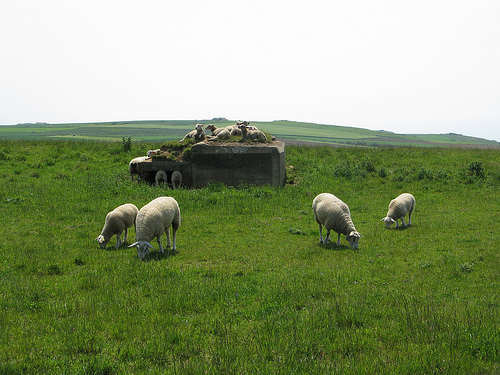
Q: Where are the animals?
A: In a field.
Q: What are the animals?
A: Sheep.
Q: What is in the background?
A: Hills.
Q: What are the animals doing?
A: Grazing.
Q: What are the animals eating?
A: Grass.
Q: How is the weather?
A: Clear.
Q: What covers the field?
A: Grass.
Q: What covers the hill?
A: Grass.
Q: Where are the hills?
A: Behind the sheep.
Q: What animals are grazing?
A: Sheep.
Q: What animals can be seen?
A: Sheep.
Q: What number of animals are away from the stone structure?
A: Four sheep.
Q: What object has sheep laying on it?
A: The concrete wall.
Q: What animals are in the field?
A: Sheep.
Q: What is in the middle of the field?
A: A stone structure.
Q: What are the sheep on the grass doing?
A: Grazing.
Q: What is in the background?
A: Green fields of grass.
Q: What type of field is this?
A: A grassy field.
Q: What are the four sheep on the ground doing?
A: Eating grass.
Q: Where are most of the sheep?
A: On the stone structure.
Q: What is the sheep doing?
A: Grazing.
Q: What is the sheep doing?
A: Eating.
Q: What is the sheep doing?
A: Standing.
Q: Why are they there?
A: Eating.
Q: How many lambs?
A: 4.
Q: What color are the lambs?
A: White.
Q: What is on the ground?
A: Grass.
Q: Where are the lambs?
A: On the grass.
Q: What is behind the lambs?
A: Building.